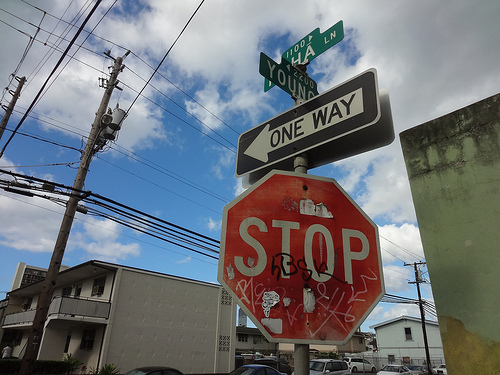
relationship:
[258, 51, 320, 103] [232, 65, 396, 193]
street sign above sign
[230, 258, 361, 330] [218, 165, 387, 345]
grafiti covering stop sign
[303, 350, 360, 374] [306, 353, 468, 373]
van parked on side of road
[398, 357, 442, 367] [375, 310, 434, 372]
fence in front of building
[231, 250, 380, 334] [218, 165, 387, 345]
graffiti on stop sign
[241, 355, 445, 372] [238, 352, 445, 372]
cars in parking lot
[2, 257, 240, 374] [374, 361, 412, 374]
building behind car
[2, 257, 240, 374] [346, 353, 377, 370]
building behind car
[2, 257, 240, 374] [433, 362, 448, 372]
building behind car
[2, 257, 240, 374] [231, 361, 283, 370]
building behind car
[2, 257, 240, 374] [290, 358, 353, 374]
building behind van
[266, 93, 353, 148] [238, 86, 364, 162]
writing on arrow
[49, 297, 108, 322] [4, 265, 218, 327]
balcony on second floor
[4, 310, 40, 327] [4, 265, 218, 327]
balcony on second floor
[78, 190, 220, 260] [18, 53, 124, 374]
wires on pole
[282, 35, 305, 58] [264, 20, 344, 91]
1100 on sign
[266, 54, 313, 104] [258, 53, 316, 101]
young on street sign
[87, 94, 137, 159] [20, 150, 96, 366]
transformers on poles